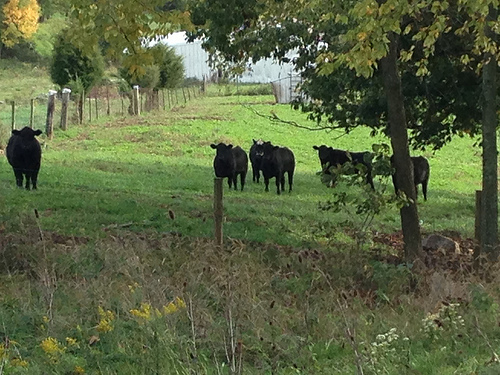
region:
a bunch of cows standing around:
[6, 115, 443, 220]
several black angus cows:
[8, 114, 450, 220]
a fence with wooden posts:
[5, 80, 209, 127]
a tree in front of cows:
[290, 4, 492, 310]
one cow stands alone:
[6, 121, 67, 196]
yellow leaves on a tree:
[3, 0, 58, 43]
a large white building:
[148, 28, 327, 128]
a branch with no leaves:
[231, 98, 383, 145]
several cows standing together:
[170, 121, 452, 219]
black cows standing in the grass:
[6, 118, 476, 227]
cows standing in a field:
[0, 123, 432, 212]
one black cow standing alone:
[3, 123, 52, 202]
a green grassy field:
[9, 79, 498, 372]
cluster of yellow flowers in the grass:
[0, 278, 190, 373]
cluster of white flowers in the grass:
[348, 298, 479, 374]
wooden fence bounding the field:
[2, 73, 214, 146]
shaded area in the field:
[1, 152, 498, 374]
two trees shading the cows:
[205, 0, 499, 282]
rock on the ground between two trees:
[421, 227, 467, 255]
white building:
[127, 22, 352, 87]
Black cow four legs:
[209, 142, 251, 190]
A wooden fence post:
[207, 174, 231, 251]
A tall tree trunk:
[362, 26, 436, 263]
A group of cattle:
[215, 125, 439, 195]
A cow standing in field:
[0, 124, 60, 194]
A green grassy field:
[76, 129, 148, 203]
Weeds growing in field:
[98, 253, 325, 361]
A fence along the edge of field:
[31, 84, 225, 122]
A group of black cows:
[190, 123, 445, 198]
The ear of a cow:
[203, 139, 220, 154]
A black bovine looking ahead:
[7, 127, 41, 188]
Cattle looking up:
[213, 142, 283, 175]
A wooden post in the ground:
[213, 178, 222, 234]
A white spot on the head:
[255, 140, 261, 145]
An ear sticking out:
[313, 145, 318, 148]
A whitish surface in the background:
[192, 46, 201, 67]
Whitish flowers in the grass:
[378, 333, 397, 341]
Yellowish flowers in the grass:
[140, 310, 165, 314]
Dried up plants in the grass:
[223, 249, 241, 301]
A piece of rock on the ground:
[427, 236, 449, 248]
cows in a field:
[10, 117, 440, 224]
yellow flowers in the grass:
[1, 288, 193, 372]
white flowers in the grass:
[337, 302, 481, 373]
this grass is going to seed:
[20, 205, 498, 372]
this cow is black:
[0, 125, 45, 190]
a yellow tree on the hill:
[0, 2, 46, 47]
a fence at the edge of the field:
[0, 74, 210, 151]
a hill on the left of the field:
[0, 0, 178, 130]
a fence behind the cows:
[267, 73, 314, 108]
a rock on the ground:
[425, 231, 462, 266]